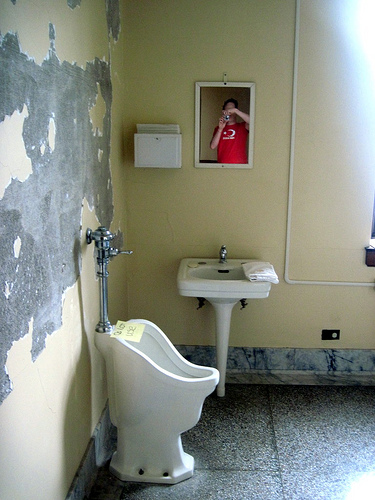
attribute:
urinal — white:
[95, 317, 219, 485]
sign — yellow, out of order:
[110, 321, 146, 343]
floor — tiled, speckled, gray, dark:
[86, 382, 374, 500]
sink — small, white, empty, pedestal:
[176, 256, 272, 300]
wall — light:
[125, 0, 374, 349]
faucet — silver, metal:
[219, 244, 229, 260]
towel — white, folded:
[241, 261, 279, 283]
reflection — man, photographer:
[211, 98, 249, 162]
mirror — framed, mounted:
[200, 88, 249, 163]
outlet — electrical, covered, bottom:
[321, 330, 340, 340]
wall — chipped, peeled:
[0, 0, 126, 499]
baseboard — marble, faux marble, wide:
[174, 344, 373, 373]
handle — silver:
[120, 249, 133, 255]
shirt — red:
[213, 123, 249, 163]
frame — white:
[194, 81, 254, 169]